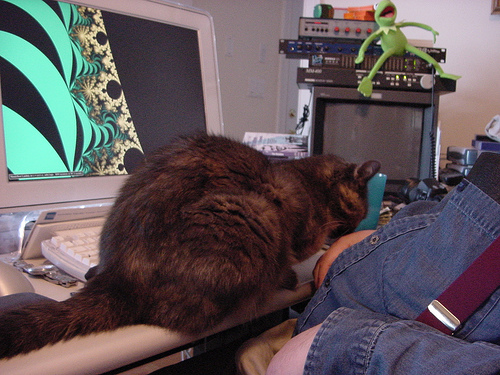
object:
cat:
[0, 129, 385, 364]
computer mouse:
[1, 257, 44, 304]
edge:
[38, 234, 96, 288]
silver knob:
[418, 75, 442, 90]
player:
[296, 67, 464, 97]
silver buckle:
[424, 297, 471, 335]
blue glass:
[351, 171, 389, 234]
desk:
[0, 216, 392, 375]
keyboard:
[39, 224, 114, 285]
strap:
[407, 239, 500, 341]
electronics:
[274, 33, 417, 61]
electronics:
[304, 50, 452, 73]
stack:
[273, 6, 461, 90]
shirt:
[292, 176, 500, 372]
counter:
[0, 251, 334, 375]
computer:
[0, 0, 234, 289]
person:
[236, 122, 500, 373]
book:
[241, 129, 308, 148]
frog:
[351, 0, 455, 101]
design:
[0, 0, 158, 184]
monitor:
[1, 0, 205, 203]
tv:
[305, 86, 452, 207]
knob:
[333, 27, 340, 32]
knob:
[344, 25, 351, 34]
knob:
[356, 26, 363, 35]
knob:
[366, 27, 373, 33]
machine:
[296, 15, 391, 39]